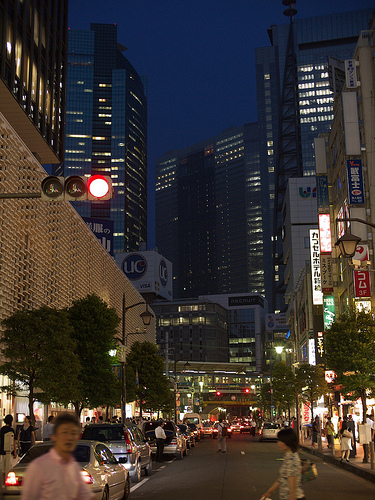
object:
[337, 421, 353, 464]
people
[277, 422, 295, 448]
hair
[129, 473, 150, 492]
line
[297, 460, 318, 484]
shoulder bag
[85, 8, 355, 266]
sky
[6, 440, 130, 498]
car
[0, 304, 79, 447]
tree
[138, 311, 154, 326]
lamp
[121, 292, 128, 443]
pole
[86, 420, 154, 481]
car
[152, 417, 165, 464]
man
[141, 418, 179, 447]
trunk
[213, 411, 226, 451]
people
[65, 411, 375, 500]
road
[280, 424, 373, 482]
sidewalk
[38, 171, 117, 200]
traffic signal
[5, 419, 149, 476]
sidewalk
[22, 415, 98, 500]
man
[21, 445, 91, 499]
shirt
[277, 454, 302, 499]
shirt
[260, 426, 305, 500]
woman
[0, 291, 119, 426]
trees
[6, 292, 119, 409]
leaves